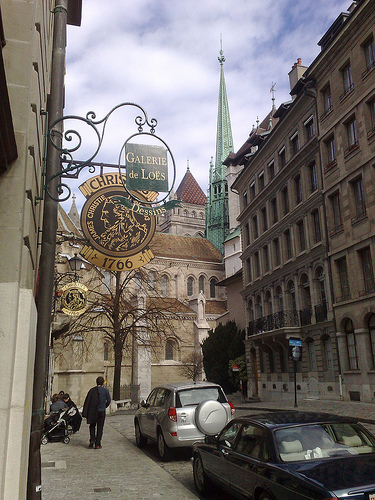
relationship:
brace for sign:
[46, 97, 157, 204] [37, 98, 177, 267]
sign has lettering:
[121, 139, 170, 194] [126, 148, 168, 182]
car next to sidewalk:
[128, 378, 236, 458] [36, 416, 203, 497]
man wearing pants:
[79, 376, 120, 446] [84, 414, 112, 447]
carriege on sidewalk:
[37, 406, 84, 447] [31, 448, 202, 499]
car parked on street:
[128, 378, 236, 458] [104, 407, 374, 495]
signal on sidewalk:
[284, 334, 307, 409] [36, 395, 214, 496]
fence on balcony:
[246, 314, 303, 327] [245, 315, 303, 337]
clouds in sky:
[105, 29, 201, 94] [64, 3, 340, 168]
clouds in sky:
[56, 0, 356, 215] [78, 9, 292, 178]